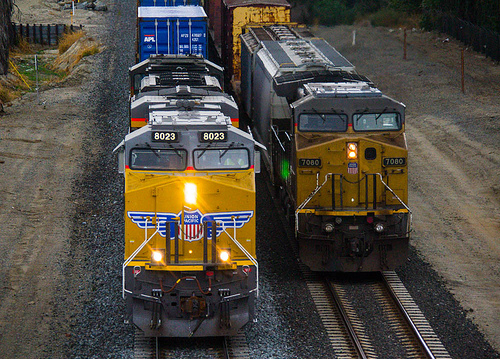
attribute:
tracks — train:
[305, 268, 451, 357]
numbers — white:
[150, 129, 177, 142]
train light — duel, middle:
[345, 141, 360, 160]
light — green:
[275, 152, 295, 183]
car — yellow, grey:
[248, 35, 415, 281]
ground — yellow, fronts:
[264, 158, 293, 202]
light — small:
[218, 249, 232, 262]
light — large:
[181, 178, 199, 206]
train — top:
[55, 10, 400, 305]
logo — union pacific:
[128, 201, 255, 249]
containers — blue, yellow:
[135, 5, 211, 62]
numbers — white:
[150, 132, 227, 146]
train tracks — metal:
[319, 302, 444, 342]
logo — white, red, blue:
[129, 208, 251, 243]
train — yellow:
[110, 1, 260, 341]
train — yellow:
[204, 0, 409, 277]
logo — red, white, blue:
[122, 206, 254, 243]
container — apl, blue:
[135, 3, 208, 63]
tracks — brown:
[153, 335, 260, 346]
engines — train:
[102, 38, 277, 356]